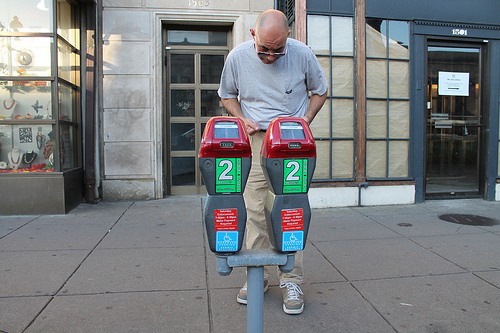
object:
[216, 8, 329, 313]
man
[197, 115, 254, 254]
meter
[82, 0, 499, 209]
building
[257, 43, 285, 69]
glasses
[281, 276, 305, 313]
shoes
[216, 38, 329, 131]
shirt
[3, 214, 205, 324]
sidewalk